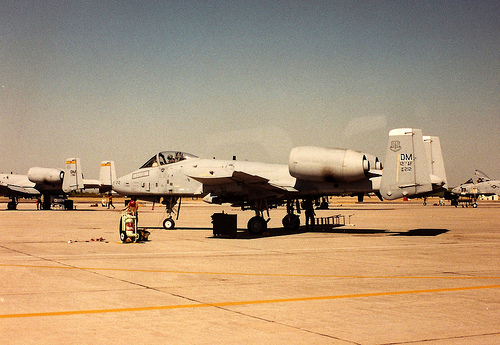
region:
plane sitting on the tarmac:
[115, 127, 462, 227]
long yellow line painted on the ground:
[3, 281, 493, 321]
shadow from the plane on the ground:
[138, 217, 449, 239]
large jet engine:
[286, 139, 364, 187]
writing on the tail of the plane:
[395, 143, 419, 180]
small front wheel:
[161, 218, 176, 230]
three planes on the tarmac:
[1, 149, 498, 244]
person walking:
[103, 194, 115, 211]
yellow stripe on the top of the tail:
[65, 160, 78, 165]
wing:
[186, 168, 266, 190]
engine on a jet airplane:
[283, 136, 373, 189]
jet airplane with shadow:
[147, 123, 463, 254]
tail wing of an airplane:
[373, 113, 470, 209]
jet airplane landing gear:
[155, 181, 186, 232]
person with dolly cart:
[113, 184, 160, 251]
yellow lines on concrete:
[8, 256, 494, 323]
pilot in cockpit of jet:
[155, 142, 198, 172]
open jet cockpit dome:
[452, 160, 499, 215]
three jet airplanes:
[5, 134, 498, 214]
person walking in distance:
[102, 188, 117, 213]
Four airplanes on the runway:
[9, 160, 494, 215]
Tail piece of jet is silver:
[389, 131, 430, 195]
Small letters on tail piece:
[399, 152, 414, 161]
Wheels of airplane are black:
[248, 215, 315, 231]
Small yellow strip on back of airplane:
[64, 159, 74, 164]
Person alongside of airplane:
[112, 200, 151, 244]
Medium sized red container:
[125, 220, 136, 239]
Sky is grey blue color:
[39, 90, 499, 143]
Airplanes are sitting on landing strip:
[16, 219, 498, 342]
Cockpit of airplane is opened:
[472, 166, 487, 187]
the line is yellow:
[230, 288, 249, 323]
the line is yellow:
[239, 292, 256, 319]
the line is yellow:
[220, 297, 240, 318]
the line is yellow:
[242, 297, 255, 305]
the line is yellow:
[247, 288, 264, 311]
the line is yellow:
[254, 270, 267, 305]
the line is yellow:
[249, 290, 254, 318]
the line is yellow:
[207, 281, 227, 313]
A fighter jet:
[110, 127, 448, 234]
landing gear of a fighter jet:
[162, 198, 301, 233]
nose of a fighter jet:
[110, 169, 141, 192]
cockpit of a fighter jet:
[137, 151, 197, 168]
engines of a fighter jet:
[288, 141, 380, 183]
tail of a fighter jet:
[380, 127, 448, 199]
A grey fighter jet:
[0, 157, 112, 208]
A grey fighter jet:
[450, 169, 497, 206]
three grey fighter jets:
[1, 127, 498, 232]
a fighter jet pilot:
[165, 151, 174, 163]